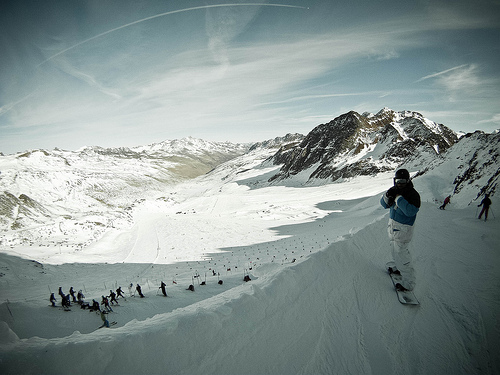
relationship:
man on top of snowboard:
[381, 168, 425, 290] [385, 260, 419, 307]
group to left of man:
[49, 280, 173, 328] [381, 168, 425, 290]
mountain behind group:
[2, 135, 254, 229] [49, 280, 173, 328]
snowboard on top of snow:
[385, 260, 419, 307] [1, 174, 500, 374]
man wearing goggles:
[381, 168, 425, 290] [394, 178, 409, 186]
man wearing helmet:
[381, 168, 425, 290] [395, 168, 410, 179]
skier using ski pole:
[158, 281, 171, 299] [155, 286, 161, 295]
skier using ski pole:
[132, 283, 145, 294] [130, 289, 137, 297]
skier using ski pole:
[473, 192, 495, 220] [489, 207, 495, 217]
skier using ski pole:
[473, 192, 495, 220] [475, 206, 480, 217]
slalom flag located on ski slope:
[217, 271, 221, 281] [0, 171, 412, 339]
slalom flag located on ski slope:
[204, 272, 208, 279] [0, 171, 412, 339]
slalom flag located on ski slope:
[215, 261, 218, 266] [0, 171, 412, 339]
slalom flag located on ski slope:
[249, 260, 252, 268] [0, 171, 412, 339]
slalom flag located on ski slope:
[285, 255, 290, 262] [0, 171, 412, 339]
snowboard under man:
[385, 260, 419, 307] [381, 168, 425, 290]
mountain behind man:
[197, 105, 467, 190] [381, 168, 425, 290]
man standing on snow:
[381, 168, 425, 290] [1, 174, 500, 374]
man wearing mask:
[381, 168, 425, 290] [394, 183, 406, 192]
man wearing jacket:
[381, 168, 425, 290] [381, 184, 420, 226]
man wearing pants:
[381, 168, 425, 290] [389, 220, 417, 291]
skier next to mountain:
[473, 192, 495, 220] [404, 131, 499, 210]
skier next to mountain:
[439, 194, 454, 211] [404, 131, 499, 210]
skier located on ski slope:
[97, 308, 117, 329] [0, 171, 412, 339]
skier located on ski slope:
[48, 292, 60, 309] [0, 171, 412, 339]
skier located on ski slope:
[68, 286, 79, 303] [0, 171, 412, 339]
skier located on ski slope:
[114, 286, 128, 303] [0, 171, 412, 339]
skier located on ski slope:
[158, 281, 171, 299] [0, 171, 412, 339]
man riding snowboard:
[381, 168, 425, 290] [385, 260, 419, 307]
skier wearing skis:
[97, 308, 117, 329] [99, 321, 116, 329]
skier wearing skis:
[473, 192, 495, 220] [473, 216, 490, 223]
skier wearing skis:
[48, 292, 60, 309] [49, 305, 60, 310]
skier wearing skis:
[132, 283, 145, 294] [132, 293, 148, 300]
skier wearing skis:
[158, 281, 171, 299] [157, 293, 170, 299]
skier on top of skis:
[97, 308, 117, 329] [99, 321, 116, 329]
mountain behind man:
[2, 135, 254, 229] [381, 168, 425, 290]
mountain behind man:
[404, 131, 499, 210] [381, 168, 425, 290]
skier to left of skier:
[439, 194, 454, 211] [473, 192, 495, 220]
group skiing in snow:
[49, 280, 173, 328] [1, 174, 500, 374]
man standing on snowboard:
[381, 168, 425, 290] [385, 260, 419, 307]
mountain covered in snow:
[2, 135, 254, 229] [1, 174, 500, 374]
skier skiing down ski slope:
[158, 281, 171, 299] [0, 171, 412, 339]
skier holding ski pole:
[473, 192, 495, 220] [489, 207, 495, 217]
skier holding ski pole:
[473, 192, 495, 220] [475, 206, 480, 217]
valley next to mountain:
[132, 172, 224, 214] [2, 135, 254, 229]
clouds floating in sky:
[0, 13, 499, 150] [0, 0, 498, 154]